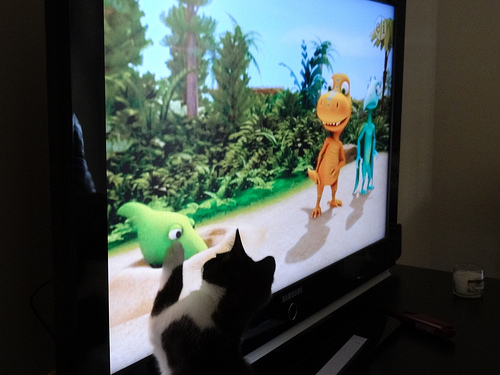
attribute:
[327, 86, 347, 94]
eyes — white, black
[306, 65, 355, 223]
animal — large, orange, blue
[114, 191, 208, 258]
animal — lime green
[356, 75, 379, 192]
animal — blue, green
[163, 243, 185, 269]
paws — white, black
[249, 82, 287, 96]
building — red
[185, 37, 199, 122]
tree base — tall, tan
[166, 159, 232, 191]
plant — green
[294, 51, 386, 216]
animals — colorful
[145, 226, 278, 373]
cat — white, black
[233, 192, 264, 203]
grass — green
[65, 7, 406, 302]
tv — samsung, big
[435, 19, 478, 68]
wall — white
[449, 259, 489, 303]
candle — white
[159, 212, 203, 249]
fish — green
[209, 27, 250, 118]
tree — green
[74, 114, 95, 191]
blob — green